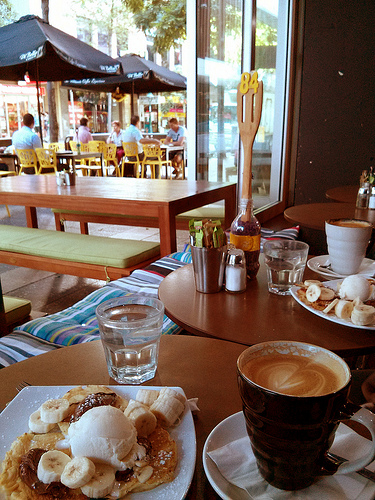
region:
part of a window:
[215, 15, 248, 66]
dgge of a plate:
[190, 456, 197, 470]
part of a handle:
[327, 427, 351, 466]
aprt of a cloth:
[239, 445, 254, 469]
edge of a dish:
[195, 427, 212, 447]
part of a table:
[214, 351, 229, 368]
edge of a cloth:
[225, 467, 239, 486]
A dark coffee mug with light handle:
[232, 337, 373, 490]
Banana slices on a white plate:
[127, 386, 188, 434]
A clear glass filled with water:
[94, 293, 164, 383]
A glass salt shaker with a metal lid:
[222, 247, 250, 294]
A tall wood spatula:
[230, 68, 266, 220]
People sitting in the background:
[9, 109, 188, 171]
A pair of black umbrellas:
[0, 11, 190, 101]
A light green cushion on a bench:
[0, 219, 168, 266]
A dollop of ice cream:
[63, 403, 148, 470]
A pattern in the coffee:
[244, 352, 338, 397]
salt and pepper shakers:
[222, 243, 246, 293]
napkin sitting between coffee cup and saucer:
[204, 338, 373, 498]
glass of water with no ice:
[95, 294, 165, 382]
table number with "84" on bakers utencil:
[228, 70, 261, 281]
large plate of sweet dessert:
[0, 383, 195, 498]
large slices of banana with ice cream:
[28, 385, 186, 497]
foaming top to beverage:
[237, 338, 349, 394]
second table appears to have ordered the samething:
[290, 219, 373, 331]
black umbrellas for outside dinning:
[0, 13, 189, 83]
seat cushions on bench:
[0, 223, 298, 373]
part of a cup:
[286, 431, 310, 462]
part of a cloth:
[233, 461, 253, 487]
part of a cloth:
[227, 453, 228, 457]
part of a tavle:
[195, 370, 217, 411]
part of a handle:
[319, 441, 339, 485]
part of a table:
[207, 374, 232, 408]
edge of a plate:
[180, 434, 195, 460]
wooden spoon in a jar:
[236, 70, 260, 217]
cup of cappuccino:
[225, 335, 357, 474]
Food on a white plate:
[21, 383, 194, 496]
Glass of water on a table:
[96, 290, 164, 378]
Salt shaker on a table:
[227, 247, 245, 293]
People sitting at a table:
[70, 111, 184, 169]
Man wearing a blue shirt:
[9, 122, 39, 154]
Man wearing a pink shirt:
[68, 122, 92, 145]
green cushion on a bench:
[26, 220, 156, 268]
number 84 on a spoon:
[239, 68, 263, 99]